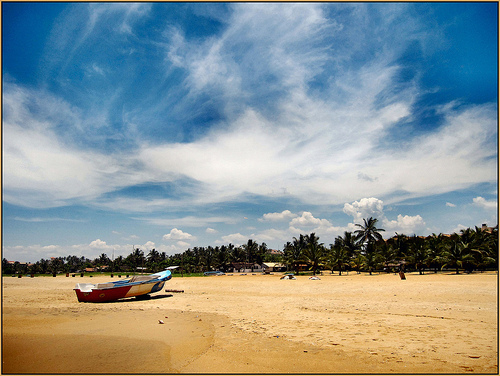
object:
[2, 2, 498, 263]
sky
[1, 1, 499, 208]
clouds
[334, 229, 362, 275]
palm tree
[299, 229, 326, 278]
palm tree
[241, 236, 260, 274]
palm tree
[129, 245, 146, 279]
palm tree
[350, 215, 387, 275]
trees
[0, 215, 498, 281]
row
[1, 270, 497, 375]
beach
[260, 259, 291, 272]
house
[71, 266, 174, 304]
boat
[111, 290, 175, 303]
shadow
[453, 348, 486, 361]
footprints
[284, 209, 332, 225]
clouds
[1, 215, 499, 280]
park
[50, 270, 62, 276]
cylinders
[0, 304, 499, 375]
marks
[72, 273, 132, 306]
back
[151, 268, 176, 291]
front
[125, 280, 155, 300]
stripe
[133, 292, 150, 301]
stone